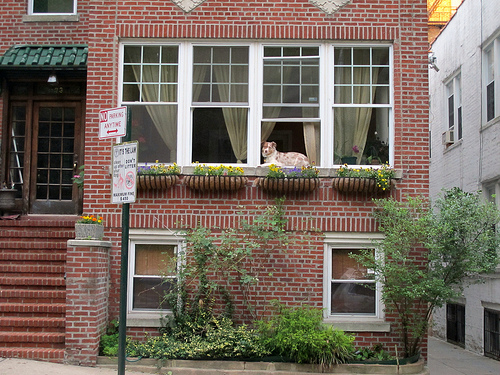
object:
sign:
[111, 142, 137, 204]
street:
[1, 358, 180, 374]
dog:
[262, 139, 310, 167]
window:
[260, 42, 321, 165]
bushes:
[177, 207, 328, 355]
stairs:
[2, 214, 72, 361]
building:
[0, 0, 432, 369]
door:
[26, 88, 83, 214]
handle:
[72, 160, 79, 173]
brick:
[91, 7, 419, 35]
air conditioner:
[441, 130, 456, 146]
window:
[429, 74, 461, 149]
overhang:
[1, 40, 89, 73]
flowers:
[196, 161, 199, 164]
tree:
[346, 185, 500, 363]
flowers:
[279, 170, 282, 172]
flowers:
[196, 348, 198, 349]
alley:
[409, 332, 493, 374]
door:
[442, 297, 465, 352]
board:
[136, 245, 176, 274]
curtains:
[126, 46, 212, 163]